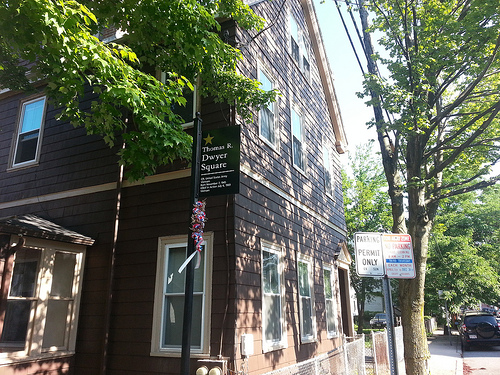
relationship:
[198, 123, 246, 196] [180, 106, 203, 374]
sign attached to pole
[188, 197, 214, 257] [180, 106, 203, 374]
flowers attached to pole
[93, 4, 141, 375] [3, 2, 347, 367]
pipe on house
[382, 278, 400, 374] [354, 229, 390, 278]
post for sign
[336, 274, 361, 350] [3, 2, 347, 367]
door to house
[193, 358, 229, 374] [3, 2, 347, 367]
meter attached to house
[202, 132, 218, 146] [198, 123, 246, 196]
star on sign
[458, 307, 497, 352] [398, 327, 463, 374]
suv along sidewalk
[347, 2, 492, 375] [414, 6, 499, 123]
trees has branches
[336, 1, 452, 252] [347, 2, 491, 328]
power lines above trees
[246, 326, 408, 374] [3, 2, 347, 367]
fence near house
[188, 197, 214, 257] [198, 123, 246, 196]
flowers under sign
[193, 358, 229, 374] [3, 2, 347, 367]
meter on front of house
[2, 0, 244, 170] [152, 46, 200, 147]
branch covering window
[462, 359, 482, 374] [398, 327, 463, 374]
leaves next to sidewalk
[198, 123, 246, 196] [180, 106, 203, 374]
sign on pole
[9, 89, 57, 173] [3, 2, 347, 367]
window on side of house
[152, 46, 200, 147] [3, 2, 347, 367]
window on side of house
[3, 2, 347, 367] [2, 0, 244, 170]
house near branch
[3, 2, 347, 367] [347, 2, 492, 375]
house beside trees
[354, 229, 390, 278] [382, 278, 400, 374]
sign on post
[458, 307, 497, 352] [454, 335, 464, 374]
suv on curb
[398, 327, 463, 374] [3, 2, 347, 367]
sidewalk beside house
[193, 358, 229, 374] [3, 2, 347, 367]
meter on house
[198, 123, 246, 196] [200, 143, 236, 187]
sign with writing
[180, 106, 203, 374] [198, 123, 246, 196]
pole holding up sign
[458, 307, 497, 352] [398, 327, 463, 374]
suv near sidewalk